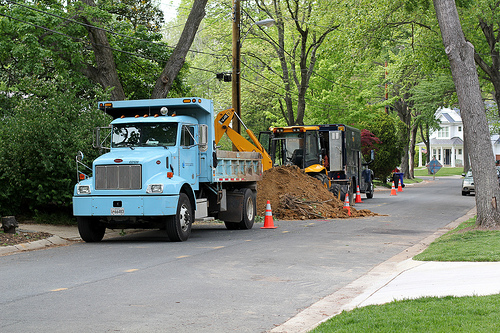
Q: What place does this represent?
A: It represents the street.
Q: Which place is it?
A: It is a street.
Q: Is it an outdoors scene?
A: Yes, it is outdoors.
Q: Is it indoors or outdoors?
A: It is outdoors.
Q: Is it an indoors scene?
A: No, it is outdoors.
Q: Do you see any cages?
A: No, there are no cages.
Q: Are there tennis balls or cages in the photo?
A: No, there are no cages or tennis balls.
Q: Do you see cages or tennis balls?
A: No, there are no cages or tennis balls.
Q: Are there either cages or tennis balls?
A: No, there are no cages or tennis balls.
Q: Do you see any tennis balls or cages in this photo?
A: No, there are no cages or tennis balls.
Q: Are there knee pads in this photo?
A: No, there are no knee pads.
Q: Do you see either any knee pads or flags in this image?
A: No, there are no knee pads or flags.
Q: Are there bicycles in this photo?
A: No, there are no bicycles.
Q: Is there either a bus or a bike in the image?
A: No, there are no bikes or buses.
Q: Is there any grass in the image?
A: Yes, there is grass.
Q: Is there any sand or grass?
A: Yes, there is grass.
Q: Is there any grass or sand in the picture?
A: Yes, there is grass.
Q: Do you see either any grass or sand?
A: Yes, there is grass.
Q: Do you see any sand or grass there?
A: Yes, there is grass.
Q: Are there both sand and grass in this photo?
A: No, there is grass but no sand.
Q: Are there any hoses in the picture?
A: No, there are no hoses.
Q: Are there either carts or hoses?
A: No, there are no hoses or carts.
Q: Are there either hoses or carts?
A: No, there are no hoses or carts.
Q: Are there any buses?
A: No, there are no buses.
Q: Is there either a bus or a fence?
A: No, there are no buses or fences.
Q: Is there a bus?
A: No, there are no buses.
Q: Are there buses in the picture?
A: No, there are no buses.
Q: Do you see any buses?
A: No, there are no buses.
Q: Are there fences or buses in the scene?
A: No, there are no buses or fences.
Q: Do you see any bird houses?
A: No, there are no bird houses.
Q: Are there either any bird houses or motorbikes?
A: No, there are no bird houses or motorbikes.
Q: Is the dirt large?
A: Yes, the dirt is large.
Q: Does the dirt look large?
A: Yes, the dirt is large.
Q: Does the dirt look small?
A: No, the dirt is large.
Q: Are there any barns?
A: No, there are no barns.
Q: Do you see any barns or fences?
A: No, there are no barns or fences.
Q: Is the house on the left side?
A: No, the house is on the right of the image.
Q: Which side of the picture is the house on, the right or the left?
A: The house is on the right of the image.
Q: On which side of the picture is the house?
A: The house is on the right of the image.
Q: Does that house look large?
A: Yes, the house is large.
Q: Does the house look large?
A: Yes, the house is large.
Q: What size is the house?
A: The house is large.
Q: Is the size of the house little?
A: No, the house is large.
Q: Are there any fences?
A: No, there are no fences.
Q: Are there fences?
A: No, there are no fences.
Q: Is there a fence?
A: No, there are no fences.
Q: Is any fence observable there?
A: No, there are no fences.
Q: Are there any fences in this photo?
A: No, there are no fences.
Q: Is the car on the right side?
A: Yes, the car is on the right of the image.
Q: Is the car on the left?
A: No, the car is on the right of the image.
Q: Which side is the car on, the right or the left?
A: The car is on the right of the image.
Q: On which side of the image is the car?
A: The car is on the right of the image.